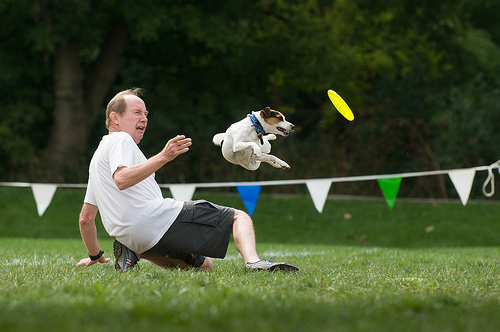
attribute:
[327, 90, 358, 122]
frisbee — bright yellow, yellow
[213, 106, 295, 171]
dog — brown, jumping, small, white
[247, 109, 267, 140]
collar — blue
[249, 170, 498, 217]
banner — multi colored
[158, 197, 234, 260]
brown shorts — deck shorts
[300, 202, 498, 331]
grass — manicured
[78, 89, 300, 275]
man — kneeling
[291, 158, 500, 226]
banner flags — triangles, roped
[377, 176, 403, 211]
flags — triangles, green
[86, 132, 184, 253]
shirt — t-shirt, short sleeve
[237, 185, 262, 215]
flag — blue